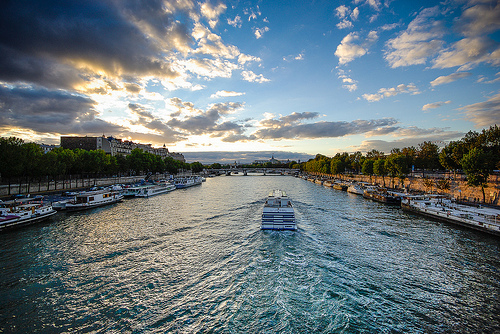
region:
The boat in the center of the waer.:
[246, 180, 306, 245]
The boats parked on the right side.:
[307, 165, 499, 276]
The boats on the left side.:
[2, 180, 222, 233]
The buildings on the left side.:
[54, 124, 170, 154]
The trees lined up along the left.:
[4, 140, 214, 177]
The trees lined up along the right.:
[308, 129, 497, 181]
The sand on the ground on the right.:
[323, 159, 499, 208]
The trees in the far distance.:
[204, 151, 304, 168]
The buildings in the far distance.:
[233, 151, 305, 165]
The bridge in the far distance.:
[204, 160, 300, 174]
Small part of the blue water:
[168, 259, 193, 279]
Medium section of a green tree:
[463, 159, 479, 173]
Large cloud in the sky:
[265, 114, 387, 138]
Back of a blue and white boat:
[261, 212, 297, 229]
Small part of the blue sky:
[283, 82, 302, 98]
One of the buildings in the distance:
[63, 137, 100, 149]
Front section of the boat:
[271, 187, 281, 191]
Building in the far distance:
[253, 155, 290, 164]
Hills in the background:
[201, 152, 247, 159]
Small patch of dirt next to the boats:
[460, 185, 477, 195]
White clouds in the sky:
[10, 3, 499, 159]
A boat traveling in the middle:
[236, 180, 336, 287]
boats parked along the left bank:
[0, 161, 210, 231]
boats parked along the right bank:
[292, 162, 497, 253]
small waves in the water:
[117, 222, 443, 330]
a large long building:
[56, 123, 192, 174]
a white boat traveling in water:
[252, 180, 305, 245]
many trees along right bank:
[297, 145, 497, 211]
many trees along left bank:
[0, 141, 185, 187]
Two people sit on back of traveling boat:
[265, 196, 294, 211]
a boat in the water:
[226, 152, 299, 260]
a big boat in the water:
[249, 180, 336, 276]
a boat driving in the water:
[239, 170, 348, 285]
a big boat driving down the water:
[233, 178, 423, 313]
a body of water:
[103, 237, 163, 297]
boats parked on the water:
[5, 170, 215, 221]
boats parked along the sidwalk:
[10, 142, 213, 230]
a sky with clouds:
[94, 35, 274, 110]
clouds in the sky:
[90, 20, 305, 155]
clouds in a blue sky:
[157, 17, 283, 136]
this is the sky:
[182, 30, 452, 110]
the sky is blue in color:
[273, 71, 312, 104]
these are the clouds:
[391, 26, 433, 53]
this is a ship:
[254, 189, 295, 227]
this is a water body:
[299, 243, 421, 327]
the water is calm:
[89, 226, 187, 306]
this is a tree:
[458, 146, 497, 198]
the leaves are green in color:
[463, 151, 489, 175]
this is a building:
[68, 134, 105, 147]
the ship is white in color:
[94, 194, 99, 201]